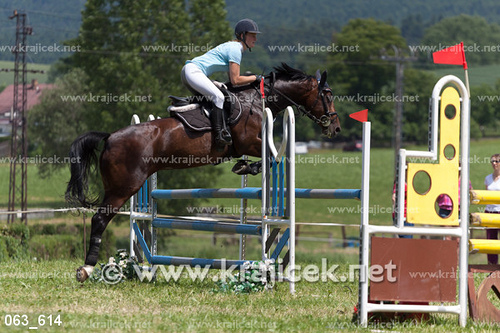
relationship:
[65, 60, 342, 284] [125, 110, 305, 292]
horse jumping over gate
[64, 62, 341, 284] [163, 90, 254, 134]
horse has saddle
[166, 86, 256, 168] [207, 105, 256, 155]
english riding boot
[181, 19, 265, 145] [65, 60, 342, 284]
female rider riding horse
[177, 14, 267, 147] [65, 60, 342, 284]
female rider over horse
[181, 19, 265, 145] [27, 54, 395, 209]
female rider riding horse